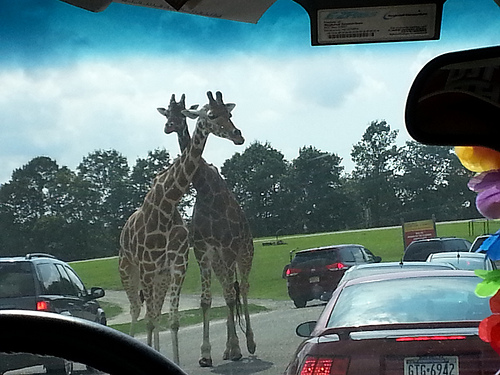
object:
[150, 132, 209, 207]
necks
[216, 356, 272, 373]
shadow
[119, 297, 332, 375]
ground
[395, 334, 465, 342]
brake light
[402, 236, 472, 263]
car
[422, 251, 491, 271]
car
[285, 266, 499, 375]
car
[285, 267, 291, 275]
light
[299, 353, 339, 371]
light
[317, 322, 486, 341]
spoiler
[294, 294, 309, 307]
wheel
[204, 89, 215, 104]
horns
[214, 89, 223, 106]
horns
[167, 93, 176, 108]
horns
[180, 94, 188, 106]
horns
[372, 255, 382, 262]
mirror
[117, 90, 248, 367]
giraffe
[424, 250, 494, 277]
car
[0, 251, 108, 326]
car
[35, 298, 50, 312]
light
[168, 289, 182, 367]
legs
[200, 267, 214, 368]
legs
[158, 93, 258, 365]
giraffe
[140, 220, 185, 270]
spots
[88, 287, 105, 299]
mirror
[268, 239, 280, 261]
grass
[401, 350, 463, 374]
license plate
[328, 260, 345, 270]
brake light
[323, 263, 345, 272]
lights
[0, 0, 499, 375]
reserve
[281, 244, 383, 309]
car